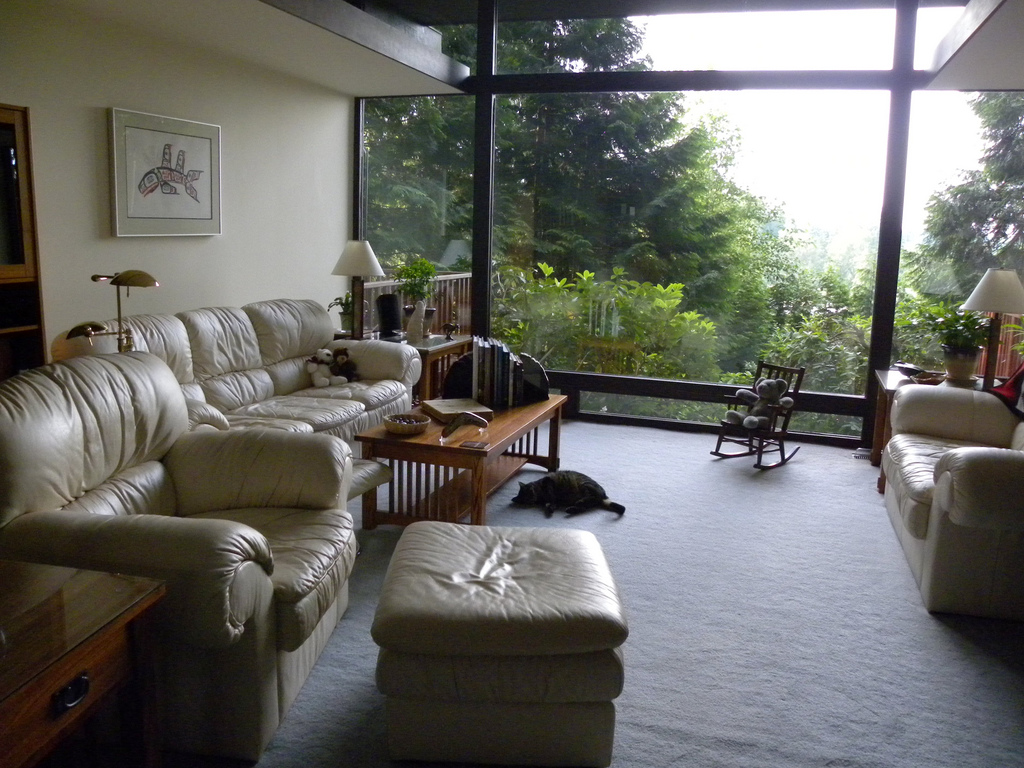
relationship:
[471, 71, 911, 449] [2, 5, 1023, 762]
window in house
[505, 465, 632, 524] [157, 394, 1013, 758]
cat on floor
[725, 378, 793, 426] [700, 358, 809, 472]
bear on chair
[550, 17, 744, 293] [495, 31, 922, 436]
tree outside window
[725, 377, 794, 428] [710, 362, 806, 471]
bear in chair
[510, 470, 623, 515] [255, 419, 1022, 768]
cat lying on floor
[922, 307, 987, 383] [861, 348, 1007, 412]
houseplant on table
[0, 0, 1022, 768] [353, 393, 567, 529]
house in coffee table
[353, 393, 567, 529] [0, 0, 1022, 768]
coffee table in house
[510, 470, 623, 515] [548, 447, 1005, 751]
cat on floor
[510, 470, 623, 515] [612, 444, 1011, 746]
cat on floor